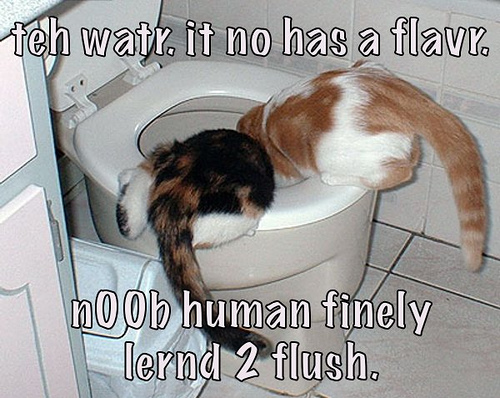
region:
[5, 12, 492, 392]
white letters on the picture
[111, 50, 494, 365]
cat's heads in the toilet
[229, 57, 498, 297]
cat is orange and white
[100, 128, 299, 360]
cat is orange black and white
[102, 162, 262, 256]
cat's paws on the toilet seat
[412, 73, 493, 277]
cat's tail hanging in air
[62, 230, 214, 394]
trash can next to toilet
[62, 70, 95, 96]
black pieces on toilet lid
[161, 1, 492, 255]
the wall is tiled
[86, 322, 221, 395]
trash bag in the can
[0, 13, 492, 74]
white writing on image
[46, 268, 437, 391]
white writing on image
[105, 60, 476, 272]
two cats next to each other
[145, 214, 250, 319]
black and brown tail of cat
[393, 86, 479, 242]
orange and brown tail of cat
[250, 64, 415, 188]
orange and white body of cat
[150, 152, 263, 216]
black and brown body of cat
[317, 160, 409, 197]
white paws of cat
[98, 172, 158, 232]
white and black paws of cat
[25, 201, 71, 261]
white hinges on door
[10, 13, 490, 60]
Purposeful misspelling of meme text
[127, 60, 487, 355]
Two cats leaning into toilet bowl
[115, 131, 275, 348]
Calico colored cat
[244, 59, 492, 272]
Orange and white colored cat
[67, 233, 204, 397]
White waste basket in bathroom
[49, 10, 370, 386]
White porcelain toilet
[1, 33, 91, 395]
Cabinets of counter in bathroom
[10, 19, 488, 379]
Text for cat meme joke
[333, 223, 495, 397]
Tiles of bathroom floor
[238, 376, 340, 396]
Grime in the grout of the bathroom floor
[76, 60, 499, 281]
two cats with heads in toilet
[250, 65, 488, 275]
back and tail of tan and white cat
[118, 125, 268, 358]
back and tail of black white and tan cat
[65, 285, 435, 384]
misspelled words n00b human finely lernd 2 flush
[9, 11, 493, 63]
misspelled words teh watr. it no has a flavr.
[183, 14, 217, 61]
the word it in white letters outlined in black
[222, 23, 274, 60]
the word no in white letters outlined in black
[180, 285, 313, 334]
the word human in white letters outlined in black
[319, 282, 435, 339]
the word finely in white letters outlined in black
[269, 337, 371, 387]
the word flush in white letters outlined in black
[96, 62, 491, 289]
2 cats drinking out of a toilet bowl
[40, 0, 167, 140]
a toilet bowl lid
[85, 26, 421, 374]
a white toilet bowl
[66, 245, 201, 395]
a small white trash can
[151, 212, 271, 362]
a black and orange cat tail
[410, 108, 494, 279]
a white and orange cat tail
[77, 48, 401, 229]
toilet bowl seat cover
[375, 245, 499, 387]
some bathroom floor tiles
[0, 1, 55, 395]
a bathroom drawer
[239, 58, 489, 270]
an orange and white cat